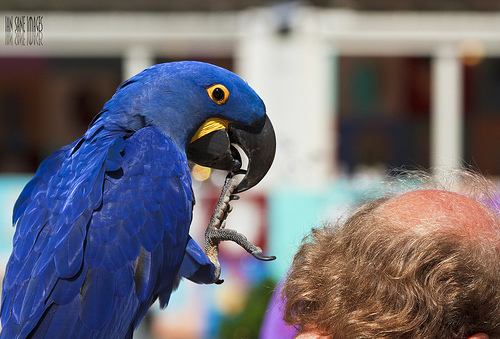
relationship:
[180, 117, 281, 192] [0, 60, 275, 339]
mouth on bird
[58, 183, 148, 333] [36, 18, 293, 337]
feather on parrot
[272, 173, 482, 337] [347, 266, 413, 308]
man with balding spot hair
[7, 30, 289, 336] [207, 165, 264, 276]
bird eating its feet